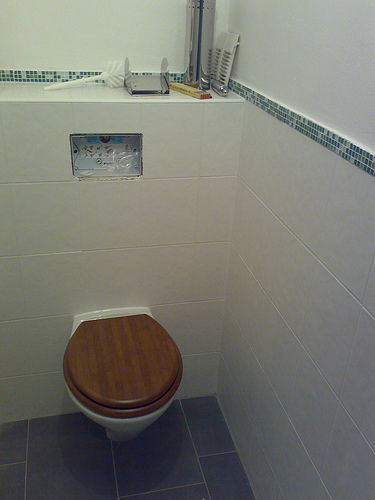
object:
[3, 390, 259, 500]
floor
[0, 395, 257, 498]
tile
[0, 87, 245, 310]
tile